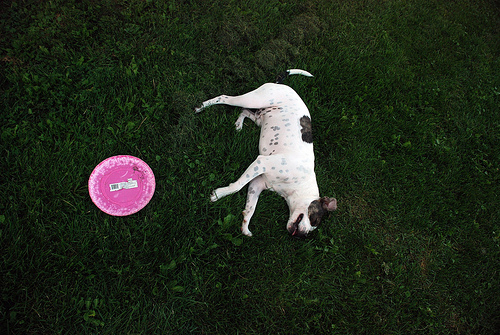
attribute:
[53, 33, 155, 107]
patch — grass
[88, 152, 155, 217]
plate — pink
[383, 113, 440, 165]
patch — green 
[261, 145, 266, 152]
spot — black 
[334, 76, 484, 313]
grass — green 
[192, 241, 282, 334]
grass — green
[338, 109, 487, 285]
grass — green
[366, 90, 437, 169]
green grass — dark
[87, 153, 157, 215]
frisbee — round 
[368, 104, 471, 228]
grass — green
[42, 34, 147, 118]
green grass — dark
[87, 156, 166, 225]
frisbee — pink 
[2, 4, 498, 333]
grass — dark green, green 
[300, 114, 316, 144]
spot — large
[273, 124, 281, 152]
spots — small